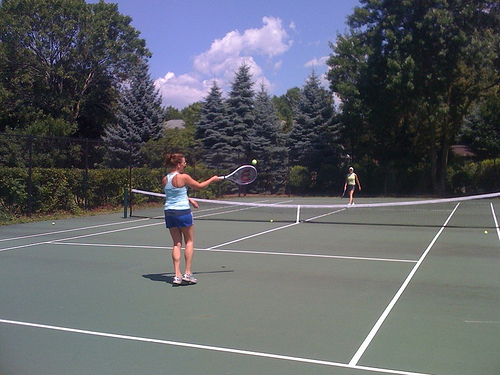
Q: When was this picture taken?
A: During the day.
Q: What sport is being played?
A: Tennis.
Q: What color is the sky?
A: Blue.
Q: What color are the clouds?
A: White.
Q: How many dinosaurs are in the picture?
A: Zero.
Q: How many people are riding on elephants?
A: Zero.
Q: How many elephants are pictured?
A: Zero.